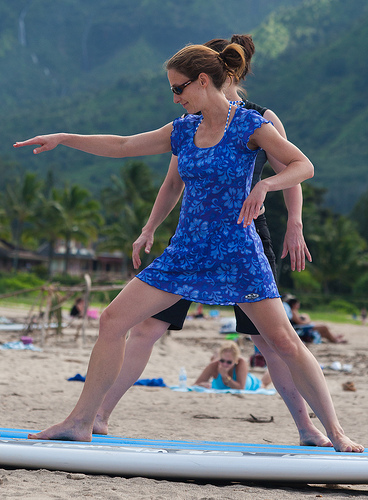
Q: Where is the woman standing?
A: On a surfboard.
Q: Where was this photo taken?
A: On a beach.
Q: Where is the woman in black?
A: Behind the woman in the dress.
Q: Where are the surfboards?
A: On the sand.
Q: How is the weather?
A: Clear and bright.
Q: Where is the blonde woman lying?
A: On a towel on the beach.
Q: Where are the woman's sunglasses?
A: On her face.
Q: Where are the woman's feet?
A: On a surfboard.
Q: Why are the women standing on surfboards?
A: To learn how to surf.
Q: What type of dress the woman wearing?
A: Floral blue dress.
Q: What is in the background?
A: Mountain.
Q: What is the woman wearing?
A: A blue dress.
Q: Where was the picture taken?
A: On a beach.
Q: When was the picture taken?
A: Daytime.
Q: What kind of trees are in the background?
A: Palm trees.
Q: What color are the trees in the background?
A: Green.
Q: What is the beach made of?
A: Sand.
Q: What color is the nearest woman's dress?
A: Blue.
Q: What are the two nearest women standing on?
A: Surf boards.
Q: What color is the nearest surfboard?
A: White.